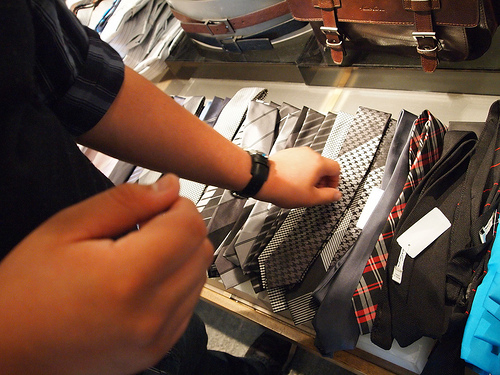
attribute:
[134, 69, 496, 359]
ties — aligned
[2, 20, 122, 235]
shirt — grey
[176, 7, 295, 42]
belt — brown, displayed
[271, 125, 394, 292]
tie — grey, spotted, black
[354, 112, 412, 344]
tie — red, plaid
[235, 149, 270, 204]
watch — black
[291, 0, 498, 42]
bag — brown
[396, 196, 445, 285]
tag — white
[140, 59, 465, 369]
shirts — piled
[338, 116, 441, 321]
stripes — diagonal, red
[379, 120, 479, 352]
tie — black, plaid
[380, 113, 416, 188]
tie — grey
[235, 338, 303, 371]
shoe — brown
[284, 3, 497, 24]
satchel — brown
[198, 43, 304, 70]
belt — black